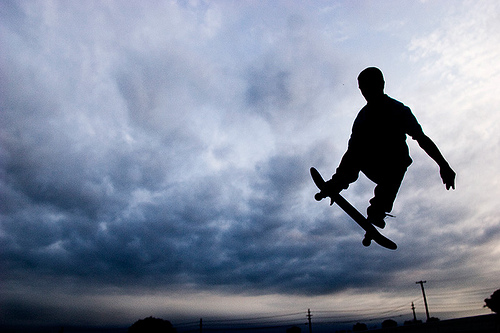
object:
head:
[357, 66, 385, 103]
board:
[308, 167, 397, 250]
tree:
[380, 319, 398, 331]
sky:
[2, 1, 499, 321]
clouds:
[2, 2, 498, 294]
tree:
[481, 288, 499, 313]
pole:
[409, 301, 417, 319]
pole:
[306, 308, 313, 332]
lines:
[200, 280, 499, 328]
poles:
[415, 280, 430, 320]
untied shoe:
[366, 202, 396, 229]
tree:
[126, 315, 178, 332]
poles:
[197, 317, 202, 329]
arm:
[405, 106, 450, 167]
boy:
[324, 66, 456, 228]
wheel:
[313, 193, 327, 202]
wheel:
[360, 237, 372, 247]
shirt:
[347, 94, 424, 166]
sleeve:
[347, 107, 364, 157]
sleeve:
[394, 105, 424, 140]